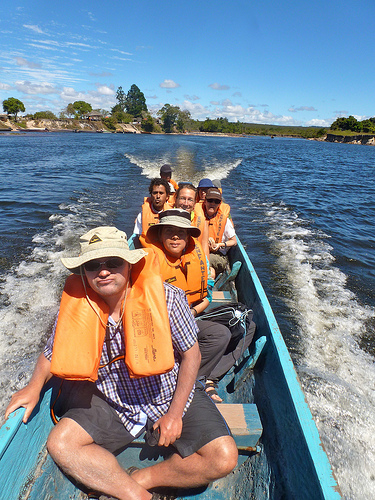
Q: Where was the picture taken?
A: It was taken at the river.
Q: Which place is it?
A: It is a river.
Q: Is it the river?
A: Yes, it is the river.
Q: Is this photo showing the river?
A: Yes, it is showing the river.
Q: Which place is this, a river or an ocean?
A: It is a river.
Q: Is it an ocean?
A: No, it is a river.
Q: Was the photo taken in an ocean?
A: No, the picture was taken in a river.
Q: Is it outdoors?
A: Yes, it is outdoors.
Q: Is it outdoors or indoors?
A: It is outdoors.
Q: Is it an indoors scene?
A: No, it is outdoors.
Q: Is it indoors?
A: No, it is outdoors.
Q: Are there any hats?
A: Yes, there is a hat.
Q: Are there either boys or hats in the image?
A: Yes, there is a hat.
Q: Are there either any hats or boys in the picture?
A: Yes, there is a hat.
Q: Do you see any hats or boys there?
A: Yes, there is a hat.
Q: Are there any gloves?
A: No, there are no gloves.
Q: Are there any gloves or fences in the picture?
A: No, there are no gloves or fences.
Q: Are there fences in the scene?
A: No, there are no fences.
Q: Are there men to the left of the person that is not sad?
A: Yes, there is a man to the left of the person.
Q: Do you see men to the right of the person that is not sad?
A: No, the man is to the left of the person.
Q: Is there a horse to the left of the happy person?
A: No, there is a man to the left of the person.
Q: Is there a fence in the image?
A: No, there are no fences.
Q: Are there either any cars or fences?
A: No, there are no fences or cars.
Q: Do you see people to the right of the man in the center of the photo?
A: Yes, there is a person to the right of the man.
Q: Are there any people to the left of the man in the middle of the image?
A: No, the person is to the right of the man.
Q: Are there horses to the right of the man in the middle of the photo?
A: No, there is a person to the right of the man.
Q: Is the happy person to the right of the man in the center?
A: Yes, the person is to the right of the man.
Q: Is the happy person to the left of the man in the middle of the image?
A: No, the person is to the right of the man.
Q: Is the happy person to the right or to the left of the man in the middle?
A: The person is to the right of the man.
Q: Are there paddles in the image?
A: No, there are no paddles.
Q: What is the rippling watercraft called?
A: The watercraft is a canoe.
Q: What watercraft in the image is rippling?
A: The watercraft is a canoe.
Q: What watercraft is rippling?
A: The watercraft is a canoe.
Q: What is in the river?
A: The kayak is in the river.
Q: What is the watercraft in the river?
A: The watercraft is a canoe.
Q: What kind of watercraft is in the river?
A: The watercraft is a canoe.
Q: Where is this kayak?
A: The kayak is in the river.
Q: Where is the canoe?
A: The kayak is in the river.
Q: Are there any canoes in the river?
A: Yes, there is a canoe in the river.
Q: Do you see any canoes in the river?
A: Yes, there is a canoe in the river.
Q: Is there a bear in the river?
A: No, there is a canoe in the river.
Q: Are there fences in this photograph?
A: No, there are no fences.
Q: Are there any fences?
A: No, there are no fences.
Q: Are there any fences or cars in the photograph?
A: No, there are no fences or cars.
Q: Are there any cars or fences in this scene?
A: No, there are no fences or cars.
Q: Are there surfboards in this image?
A: No, there are no surfboards.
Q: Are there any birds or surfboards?
A: No, there are no surfboards or birds.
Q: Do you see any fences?
A: No, there are no fences.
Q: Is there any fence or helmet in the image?
A: No, there are no fences or helmets.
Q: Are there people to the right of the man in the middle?
A: Yes, there is a person to the right of the man.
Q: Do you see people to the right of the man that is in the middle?
A: Yes, there is a person to the right of the man.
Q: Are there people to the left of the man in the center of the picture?
A: No, the person is to the right of the man.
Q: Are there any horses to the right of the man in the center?
A: No, there is a person to the right of the man.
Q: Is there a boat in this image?
A: Yes, there is a boat.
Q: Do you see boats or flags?
A: Yes, there is a boat.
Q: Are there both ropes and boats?
A: No, there is a boat but no ropes.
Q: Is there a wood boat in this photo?
A: Yes, there is a wood boat.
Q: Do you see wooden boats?
A: Yes, there is a wood boat.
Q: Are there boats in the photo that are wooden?
A: Yes, there is a boat that is wooden.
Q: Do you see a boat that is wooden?
A: Yes, there is a boat that is wooden.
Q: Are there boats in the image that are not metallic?
A: Yes, there is a wooden boat.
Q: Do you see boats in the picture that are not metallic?
A: Yes, there is a wooden boat.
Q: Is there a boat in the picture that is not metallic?
A: Yes, there is a wooden boat.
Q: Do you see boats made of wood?
A: Yes, there is a boat that is made of wood.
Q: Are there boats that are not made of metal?
A: Yes, there is a boat that is made of wood.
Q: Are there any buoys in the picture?
A: No, there are no buoys.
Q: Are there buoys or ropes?
A: No, there are no buoys or ropes.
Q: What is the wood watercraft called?
A: The watercraft is a boat.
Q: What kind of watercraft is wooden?
A: The watercraft is a boat.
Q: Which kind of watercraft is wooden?
A: The watercraft is a boat.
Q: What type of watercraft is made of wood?
A: The watercraft is a boat.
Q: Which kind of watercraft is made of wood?
A: The watercraft is a boat.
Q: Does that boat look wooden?
A: Yes, the boat is wooden.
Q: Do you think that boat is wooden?
A: Yes, the boat is wooden.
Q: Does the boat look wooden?
A: Yes, the boat is wooden.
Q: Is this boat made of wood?
A: Yes, the boat is made of wood.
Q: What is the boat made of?
A: The boat is made of wood.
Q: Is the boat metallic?
A: No, the boat is wooden.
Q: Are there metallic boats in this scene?
A: No, there is a boat but it is wooden.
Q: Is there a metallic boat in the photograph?
A: No, there is a boat but it is wooden.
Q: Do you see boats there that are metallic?
A: No, there is a boat but it is wooden.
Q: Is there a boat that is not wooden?
A: No, there is a boat but it is wooden.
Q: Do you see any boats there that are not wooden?
A: No, there is a boat but it is wooden.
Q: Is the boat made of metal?
A: No, the boat is made of wood.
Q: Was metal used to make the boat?
A: No, the boat is made of wood.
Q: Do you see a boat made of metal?
A: No, there is a boat but it is made of wood.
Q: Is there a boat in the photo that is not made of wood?
A: No, there is a boat but it is made of wood.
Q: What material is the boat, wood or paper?
A: The boat is made of wood.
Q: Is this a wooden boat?
A: Yes, this is a wooden boat.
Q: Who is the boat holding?
A: The boat is holding the people.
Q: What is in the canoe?
A: The boat is in the canoe.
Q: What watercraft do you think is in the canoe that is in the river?
A: The watercraft is a boat.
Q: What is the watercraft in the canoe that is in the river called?
A: The watercraft is a boat.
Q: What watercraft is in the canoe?
A: The watercraft is a boat.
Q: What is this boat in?
A: The boat is in the kayak.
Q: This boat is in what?
A: The boat is in the kayak.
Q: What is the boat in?
A: The boat is in the kayak.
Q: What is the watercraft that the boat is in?
A: The watercraft is a canoe.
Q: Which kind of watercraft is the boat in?
A: The boat is in the kayak.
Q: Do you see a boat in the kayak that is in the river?
A: Yes, there is a boat in the kayak.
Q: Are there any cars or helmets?
A: No, there are no cars or helmets.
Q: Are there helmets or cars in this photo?
A: No, there are no cars or helmets.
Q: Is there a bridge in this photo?
A: No, there are no bridges.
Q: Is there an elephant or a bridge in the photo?
A: No, there are no bridges or elephants.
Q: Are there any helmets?
A: No, there are no helmets.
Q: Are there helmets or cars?
A: No, there are no helmets or cars.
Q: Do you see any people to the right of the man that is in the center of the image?
A: Yes, there is a person to the right of the man.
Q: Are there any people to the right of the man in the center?
A: Yes, there is a person to the right of the man.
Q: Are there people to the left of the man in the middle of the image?
A: No, the person is to the right of the man.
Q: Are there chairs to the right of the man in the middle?
A: No, there is a person to the right of the man.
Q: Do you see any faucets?
A: No, there are no faucets.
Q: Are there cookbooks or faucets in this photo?
A: No, there are no faucets or cookbooks.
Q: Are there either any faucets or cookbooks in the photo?
A: No, there are no faucets or cookbooks.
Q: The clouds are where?
A: The clouds are in the sky.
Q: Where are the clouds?
A: The clouds are in the sky.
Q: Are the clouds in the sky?
A: Yes, the clouds are in the sky.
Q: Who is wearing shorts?
A: The man is wearing shorts.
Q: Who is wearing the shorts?
A: The man is wearing shorts.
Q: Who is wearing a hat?
A: The man is wearing a hat.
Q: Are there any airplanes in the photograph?
A: No, there are no airplanes.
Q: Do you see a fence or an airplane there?
A: No, there are no airplanes or fences.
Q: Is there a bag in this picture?
A: Yes, there is a bag.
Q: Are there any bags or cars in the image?
A: Yes, there is a bag.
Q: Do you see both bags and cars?
A: No, there is a bag but no cars.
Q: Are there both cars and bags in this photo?
A: No, there is a bag but no cars.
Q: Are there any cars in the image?
A: No, there are no cars.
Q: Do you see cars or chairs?
A: No, there are no cars or chairs.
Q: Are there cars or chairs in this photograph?
A: No, there are no cars or chairs.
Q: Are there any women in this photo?
A: Yes, there is a woman.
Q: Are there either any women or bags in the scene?
A: Yes, there is a woman.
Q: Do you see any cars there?
A: No, there are no cars.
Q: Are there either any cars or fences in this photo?
A: No, there are no cars or fences.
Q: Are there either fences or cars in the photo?
A: No, there are no cars or fences.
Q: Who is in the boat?
A: The people are in the boat.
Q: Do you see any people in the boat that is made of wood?
A: Yes, there are people in the boat.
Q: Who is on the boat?
A: The people are on the boat.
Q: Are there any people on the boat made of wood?
A: Yes, there are people on the boat.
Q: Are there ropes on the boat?
A: No, there are people on the boat.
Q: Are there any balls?
A: No, there are no balls.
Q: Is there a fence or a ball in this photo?
A: No, there are no balls or fences.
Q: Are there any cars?
A: No, there are no cars.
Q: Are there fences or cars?
A: No, there are no cars or fences.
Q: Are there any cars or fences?
A: No, there are no cars or fences.